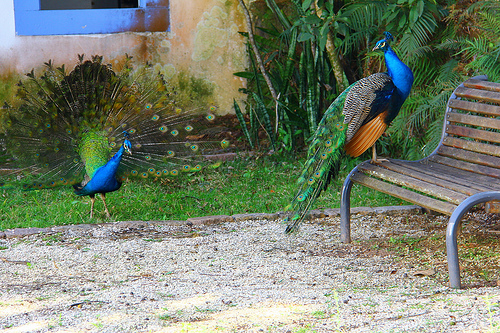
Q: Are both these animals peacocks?
A: Yes, all the animals are peacocks.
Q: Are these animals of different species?
A: No, all the animals are peacocks.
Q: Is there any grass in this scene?
A: Yes, there is grass.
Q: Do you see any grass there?
A: Yes, there is grass.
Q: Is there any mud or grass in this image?
A: Yes, there is grass.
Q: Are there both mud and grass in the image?
A: No, there is grass but no mud.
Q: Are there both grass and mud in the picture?
A: No, there is grass but no mud.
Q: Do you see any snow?
A: No, there is no snow.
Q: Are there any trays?
A: No, there are no trays.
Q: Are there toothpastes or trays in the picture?
A: No, there are no trays or toothpastes.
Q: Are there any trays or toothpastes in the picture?
A: No, there are no trays or toothpastes.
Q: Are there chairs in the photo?
A: No, there are no chairs.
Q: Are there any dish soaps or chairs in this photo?
A: No, there are no chairs or dish soaps.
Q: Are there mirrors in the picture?
A: No, there are no mirrors.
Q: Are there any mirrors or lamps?
A: No, there are no mirrors or lamps.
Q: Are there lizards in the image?
A: No, there are no lizards.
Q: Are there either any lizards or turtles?
A: No, there are no lizards or turtles.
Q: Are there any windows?
A: Yes, there is a window.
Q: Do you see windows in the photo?
A: Yes, there is a window.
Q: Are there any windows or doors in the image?
A: Yes, there is a window.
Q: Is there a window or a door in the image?
A: Yes, there is a window.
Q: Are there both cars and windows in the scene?
A: No, there is a window but no cars.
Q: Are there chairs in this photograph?
A: No, there are no chairs.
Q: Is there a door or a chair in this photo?
A: No, there are no chairs or doors.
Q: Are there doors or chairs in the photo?
A: No, there are no chairs or doors.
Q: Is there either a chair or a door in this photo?
A: No, there are no chairs or doors.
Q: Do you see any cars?
A: No, there are no cars.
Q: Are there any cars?
A: No, there are no cars.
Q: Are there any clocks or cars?
A: No, there are no cars or clocks.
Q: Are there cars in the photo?
A: No, there are no cars.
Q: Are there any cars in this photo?
A: No, there are no cars.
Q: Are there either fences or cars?
A: No, there are no cars or fences.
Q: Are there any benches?
A: Yes, there is a bench.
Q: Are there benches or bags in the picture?
A: Yes, there is a bench.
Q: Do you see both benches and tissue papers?
A: No, there is a bench but no tissues.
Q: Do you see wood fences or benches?
A: Yes, there is a wood bench.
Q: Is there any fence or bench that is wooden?
A: Yes, the bench is wooden.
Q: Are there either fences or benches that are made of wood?
A: Yes, the bench is made of wood.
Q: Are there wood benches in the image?
A: Yes, there is a wood bench.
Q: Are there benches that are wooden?
A: Yes, there is a bench that is wooden.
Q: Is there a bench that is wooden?
A: Yes, there is a bench that is wooden.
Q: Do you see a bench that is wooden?
A: Yes, there is a bench that is wooden.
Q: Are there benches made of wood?
A: Yes, there is a bench that is made of wood.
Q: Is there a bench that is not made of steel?
A: Yes, there is a bench that is made of wood.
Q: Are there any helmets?
A: No, there are no helmets.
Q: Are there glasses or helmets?
A: No, there are no helmets or glasses.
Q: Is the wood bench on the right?
A: Yes, the bench is on the right of the image.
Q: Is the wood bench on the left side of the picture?
A: No, the bench is on the right of the image.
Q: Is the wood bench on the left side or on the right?
A: The bench is on the right of the image.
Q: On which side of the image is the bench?
A: The bench is on the right of the image.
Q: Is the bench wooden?
A: Yes, the bench is wooden.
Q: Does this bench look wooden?
A: Yes, the bench is wooden.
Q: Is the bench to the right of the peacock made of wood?
A: Yes, the bench is made of wood.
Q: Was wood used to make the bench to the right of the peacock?
A: Yes, the bench is made of wood.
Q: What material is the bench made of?
A: The bench is made of wood.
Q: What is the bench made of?
A: The bench is made of wood.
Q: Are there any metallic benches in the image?
A: No, there is a bench but it is wooden.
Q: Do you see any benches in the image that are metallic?
A: No, there is a bench but it is wooden.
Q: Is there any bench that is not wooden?
A: No, there is a bench but it is wooden.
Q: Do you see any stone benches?
A: No, there is a bench but it is made of wood.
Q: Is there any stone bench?
A: No, there is a bench but it is made of wood.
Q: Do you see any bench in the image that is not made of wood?
A: No, there is a bench but it is made of wood.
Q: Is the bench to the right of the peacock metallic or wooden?
A: The bench is wooden.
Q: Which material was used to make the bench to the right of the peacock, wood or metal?
A: The bench is made of wood.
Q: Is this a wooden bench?
A: Yes, this is a wooden bench.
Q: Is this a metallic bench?
A: No, this is a wooden bench.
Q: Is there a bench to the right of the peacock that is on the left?
A: Yes, there is a bench to the right of the peacock.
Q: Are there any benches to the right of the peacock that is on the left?
A: Yes, there is a bench to the right of the peacock.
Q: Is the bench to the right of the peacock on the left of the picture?
A: Yes, the bench is to the right of the peacock.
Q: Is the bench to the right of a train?
A: No, the bench is to the right of the peacock.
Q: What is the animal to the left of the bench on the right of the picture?
A: The animal is a peacock.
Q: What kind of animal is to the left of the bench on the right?
A: The animal is a peacock.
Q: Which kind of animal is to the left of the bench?
A: The animal is a peacock.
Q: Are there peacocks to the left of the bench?
A: Yes, there is a peacock to the left of the bench.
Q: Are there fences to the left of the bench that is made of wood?
A: No, there is a peacock to the left of the bench.